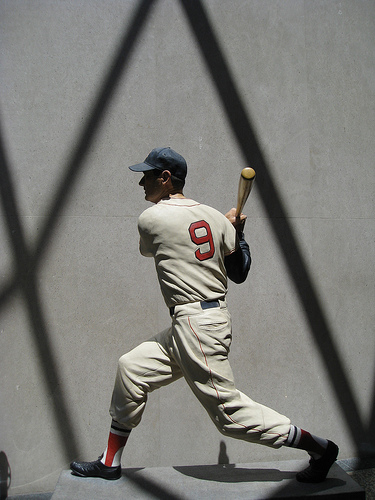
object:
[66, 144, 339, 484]
baseball player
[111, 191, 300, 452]
uniform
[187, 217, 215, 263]
number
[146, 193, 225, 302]
back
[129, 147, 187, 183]
cap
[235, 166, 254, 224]
bat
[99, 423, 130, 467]
sock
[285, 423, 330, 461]
sock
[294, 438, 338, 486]
shoe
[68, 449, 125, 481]
shoe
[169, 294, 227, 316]
belt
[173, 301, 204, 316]
buckle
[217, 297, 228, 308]
buckle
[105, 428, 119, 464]
line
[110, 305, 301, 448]
pants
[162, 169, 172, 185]
ear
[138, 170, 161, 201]
face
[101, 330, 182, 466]
leg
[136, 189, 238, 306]
shirt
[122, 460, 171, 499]
shadow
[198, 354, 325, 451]
leg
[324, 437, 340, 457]
heel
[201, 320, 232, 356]
pocket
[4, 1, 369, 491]
shadow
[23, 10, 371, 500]
background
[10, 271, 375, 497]
ground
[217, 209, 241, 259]
sleeve